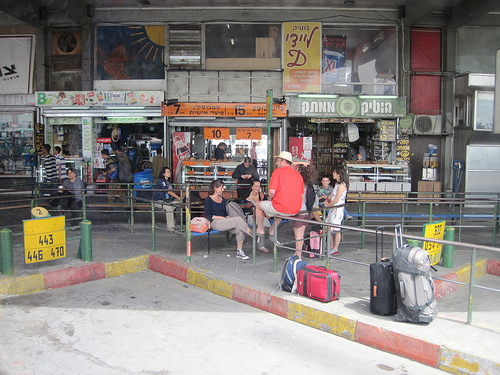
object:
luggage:
[371, 222, 396, 316]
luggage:
[295, 261, 342, 304]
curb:
[151, 252, 498, 373]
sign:
[20, 211, 69, 265]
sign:
[278, 17, 327, 99]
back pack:
[277, 251, 306, 296]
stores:
[32, 111, 176, 205]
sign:
[32, 88, 169, 109]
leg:
[209, 216, 257, 239]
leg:
[227, 228, 249, 259]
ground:
[0, 223, 500, 375]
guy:
[253, 149, 306, 238]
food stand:
[161, 97, 290, 197]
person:
[321, 165, 351, 259]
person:
[152, 164, 188, 231]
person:
[202, 177, 258, 262]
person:
[231, 156, 263, 202]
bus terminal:
[4, 0, 497, 375]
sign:
[288, 96, 405, 118]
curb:
[0, 248, 157, 304]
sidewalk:
[0, 205, 500, 375]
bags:
[388, 222, 437, 326]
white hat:
[271, 150, 295, 165]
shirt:
[261, 162, 307, 219]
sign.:
[279, 15, 328, 99]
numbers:
[24, 247, 45, 263]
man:
[250, 146, 306, 240]